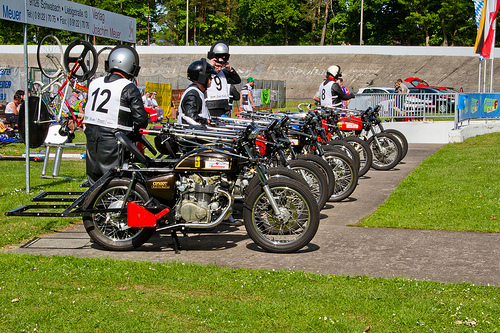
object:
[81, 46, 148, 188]
man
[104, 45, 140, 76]
helmet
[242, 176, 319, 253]
tire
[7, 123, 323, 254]
motorcycle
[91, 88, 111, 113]
number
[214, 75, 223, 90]
number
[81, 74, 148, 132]
coat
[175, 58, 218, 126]
man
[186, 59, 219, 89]
helmet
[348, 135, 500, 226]
grass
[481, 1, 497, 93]
flags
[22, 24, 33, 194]
pole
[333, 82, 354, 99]
arm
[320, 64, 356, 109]
man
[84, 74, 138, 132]
vest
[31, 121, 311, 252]
motorcycles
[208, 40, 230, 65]
helmet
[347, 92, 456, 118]
fence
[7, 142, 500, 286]
path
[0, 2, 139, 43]
sign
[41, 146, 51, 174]
poles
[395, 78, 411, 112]
people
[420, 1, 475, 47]
trees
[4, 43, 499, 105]
wall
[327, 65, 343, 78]
helmet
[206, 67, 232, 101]
vest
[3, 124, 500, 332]
grass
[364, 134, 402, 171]
wheels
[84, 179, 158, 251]
wheels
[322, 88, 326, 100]
number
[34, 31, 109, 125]
bikes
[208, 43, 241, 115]
people